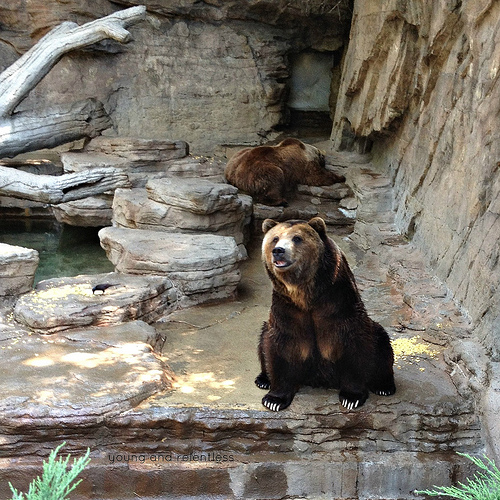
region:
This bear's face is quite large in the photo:
[271, 223, 308, 307]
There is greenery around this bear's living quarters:
[453, 460, 483, 468]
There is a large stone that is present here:
[122, 190, 159, 300]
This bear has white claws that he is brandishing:
[262, 391, 280, 410]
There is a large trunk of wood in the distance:
[38, 31, 72, 102]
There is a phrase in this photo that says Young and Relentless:
[113, 443, 195, 493]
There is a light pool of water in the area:
[44, 245, 76, 293]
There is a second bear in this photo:
[233, 145, 323, 198]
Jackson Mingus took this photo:
[96, 62, 418, 437]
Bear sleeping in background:
[220, 141, 340, 199]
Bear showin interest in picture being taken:
[253, 209, 398, 411]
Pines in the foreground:
[17, 443, 80, 499]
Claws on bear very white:
[258, 397, 296, 413]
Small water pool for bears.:
[9, 214, 113, 268]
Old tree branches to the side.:
[5, 10, 131, 195]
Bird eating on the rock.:
[84, 281, 117, 298]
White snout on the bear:
[270, 239, 296, 263]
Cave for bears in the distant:
[278, 102, 336, 137]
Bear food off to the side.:
[391, 332, 438, 364]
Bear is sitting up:
[250, 212, 401, 417]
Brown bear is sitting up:
[253, 211, 403, 416]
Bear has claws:
[252, 377, 399, 416]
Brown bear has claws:
[246, 377, 398, 414]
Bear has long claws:
[252, 372, 400, 413]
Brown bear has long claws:
[249, 375, 401, 412]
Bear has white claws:
[252, 376, 399, 416]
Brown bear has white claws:
[250, 379, 399, 412]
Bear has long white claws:
[250, 376, 399, 413]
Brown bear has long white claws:
[252, 373, 399, 413]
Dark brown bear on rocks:
[245, 216, 383, 426]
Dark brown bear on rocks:
[205, 109, 342, 225]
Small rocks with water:
[33, 400, 135, 454]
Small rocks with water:
[134, 383, 235, 440]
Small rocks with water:
[228, 385, 354, 460]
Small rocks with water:
[30, 255, 193, 340]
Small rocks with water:
[108, 200, 232, 302]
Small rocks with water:
[90, 163, 267, 228]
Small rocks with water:
[75, 136, 192, 184]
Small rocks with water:
[329, 39, 464, 211]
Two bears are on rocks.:
[210, 118, 412, 401]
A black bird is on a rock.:
[85, 279, 134, 304]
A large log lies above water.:
[2, 9, 182, 241]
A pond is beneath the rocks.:
[7, 193, 122, 289]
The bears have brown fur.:
[236, 135, 372, 346]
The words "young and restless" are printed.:
[105, 453, 240, 474]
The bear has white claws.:
[256, 363, 425, 423]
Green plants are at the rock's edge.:
[8, 428, 497, 498]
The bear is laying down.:
[221, 130, 351, 204]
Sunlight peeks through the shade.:
[24, 330, 249, 427]